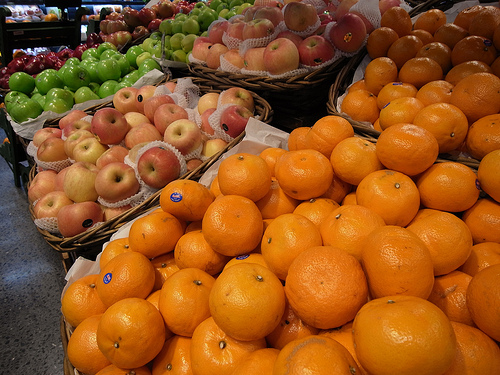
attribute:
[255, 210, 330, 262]
orange — unpeeled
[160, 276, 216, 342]
orange — unpeeled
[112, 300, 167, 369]
orange — unpeeled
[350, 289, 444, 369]
orange — unpeeled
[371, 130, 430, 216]
orange — unpeeled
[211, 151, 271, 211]
orange — unpeeled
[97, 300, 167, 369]
orange — unpeeled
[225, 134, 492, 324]
orange — unpeeled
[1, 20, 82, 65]
table — wooden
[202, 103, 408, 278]
orange — unpeeled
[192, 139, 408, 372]
apples — green 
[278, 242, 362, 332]
orange — unpeeled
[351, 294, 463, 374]
orange — unpeeled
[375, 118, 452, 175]
orange — unpeeled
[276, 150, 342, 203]
orange — unpeeled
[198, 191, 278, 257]
orange — unpeeled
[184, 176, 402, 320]
orange — unpeeled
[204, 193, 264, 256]
orange — unpeeled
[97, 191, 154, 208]
cup — paper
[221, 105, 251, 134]
apple — green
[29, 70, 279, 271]
basket — brown